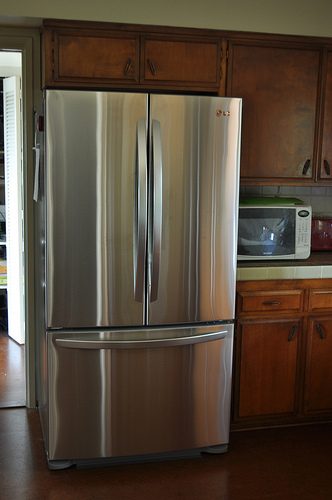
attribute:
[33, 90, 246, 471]
refrigerator — steel, silver, reflecting', tall, reflecting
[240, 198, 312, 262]
microwave — small, white, reflecting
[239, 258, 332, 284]
counter — white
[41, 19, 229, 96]
cabinet — small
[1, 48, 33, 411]
door — white, open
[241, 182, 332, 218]
backsplash — white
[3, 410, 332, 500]
floor — smooth, brown, reflecting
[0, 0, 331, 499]
kitchen — wooden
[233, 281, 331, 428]
cabinets — brown, wood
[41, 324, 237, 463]
drawer — big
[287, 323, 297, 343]
handle — black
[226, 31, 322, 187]
cabinet — wooden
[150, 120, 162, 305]
handle — metal